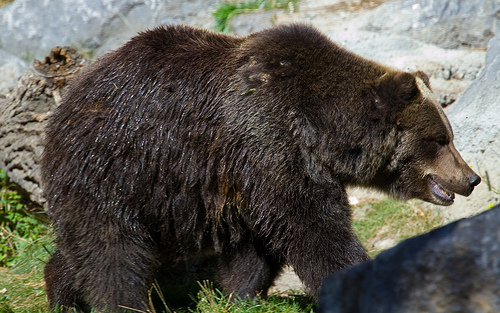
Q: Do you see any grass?
A: Yes, there is grass.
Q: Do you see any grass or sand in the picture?
A: Yes, there is grass.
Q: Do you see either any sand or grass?
A: Yes, there is grass.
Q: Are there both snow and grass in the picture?
A: No, there is grass but no snow.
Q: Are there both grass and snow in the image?
A: No, there is grass but no snow.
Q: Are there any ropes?
A: No, there are no ropes.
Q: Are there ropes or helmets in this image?
A: No, there are no ropes or helmets.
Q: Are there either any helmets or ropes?
A: No, there are no ropes or helmets.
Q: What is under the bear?
A: The grass is under the bear.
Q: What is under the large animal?
A: The grass is under the bear.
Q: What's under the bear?
A: The grass is under the bear.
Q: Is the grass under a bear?
A: Yes, the grass is under a bear.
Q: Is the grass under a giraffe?
A: No, the grass is under a bear.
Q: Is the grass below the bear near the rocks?
A: Yes, the grass is below the bear.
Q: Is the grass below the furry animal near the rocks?
A: Yes, the grass is below the bear.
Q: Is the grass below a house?
A: No, the grass is below the bear.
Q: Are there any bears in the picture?
A: Yes, there is a bear.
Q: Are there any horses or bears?
A: Yes, there is a bear.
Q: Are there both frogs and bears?
A: No, there is a bear but no frogs.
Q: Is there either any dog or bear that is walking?
A: Yes, the bear is walking.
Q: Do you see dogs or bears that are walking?
A: Yes, the bear is walking.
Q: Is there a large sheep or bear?
A: Yes, there is a large bear.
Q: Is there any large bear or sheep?
A: Yes, there is a large bear.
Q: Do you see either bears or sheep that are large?
A: Yes, the bear is large.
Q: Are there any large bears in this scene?
A: Yes, there is a large bear.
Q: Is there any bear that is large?
A: Yes, there is a bear that is large.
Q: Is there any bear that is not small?
A: Yes, there is a large bear.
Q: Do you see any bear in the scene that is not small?
A: Yes, there is a large bear.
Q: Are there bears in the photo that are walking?
A: Yes, there is a bear that is walking.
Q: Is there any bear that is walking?
A: Yes, there is a bear that is walking.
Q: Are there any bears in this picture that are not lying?
A: Yes, there is a bear that is walking.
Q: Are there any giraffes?
A: No, there are no giraffes.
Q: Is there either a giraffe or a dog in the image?
A: No, there are no giraffes or dogs.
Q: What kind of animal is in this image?
A: The animal is a bear.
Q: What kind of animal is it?
A: The animal is a bear.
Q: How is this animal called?
A: This is a bear.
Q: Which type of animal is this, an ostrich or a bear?
A: This is a bear.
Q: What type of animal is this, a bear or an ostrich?
A: This is a bear.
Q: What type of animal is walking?
A: The animal is a bear.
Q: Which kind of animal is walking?
A: The animal is a bear.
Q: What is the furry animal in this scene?
A: The animal is a bear.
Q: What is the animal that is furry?
A: The animal is a bear.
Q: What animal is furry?
A: The animal is a bear.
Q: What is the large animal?
A: The animal is a bear.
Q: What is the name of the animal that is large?
A: The animal is a bear.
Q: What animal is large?
A: The animal is a bear.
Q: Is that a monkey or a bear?
A: That is a bear.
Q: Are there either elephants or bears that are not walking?
A: No, there is a bear but it is walking.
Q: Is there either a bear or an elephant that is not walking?
A: No, there is a bear but it is walking.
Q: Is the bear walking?
A: Yes, the bear is walking.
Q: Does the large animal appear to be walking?
A: Yes, the bear is walking.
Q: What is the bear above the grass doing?
A: The bear is walking.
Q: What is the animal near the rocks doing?
A: The bear is walking.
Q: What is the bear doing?
A: The bear is walking.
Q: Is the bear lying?
A: No, the bear is walking.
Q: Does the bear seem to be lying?
A: No, the bear is walking.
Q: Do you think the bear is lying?
A: No, the bear is walking.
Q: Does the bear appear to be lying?
A: No, the bear is walking.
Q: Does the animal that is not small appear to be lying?
A: No, the bear is walking.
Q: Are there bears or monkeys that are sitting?
A: No, there is a bear but it is walking.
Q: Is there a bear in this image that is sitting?
A: No, there is a bear but it is walking.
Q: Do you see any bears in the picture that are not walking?
A: No, there is a bear but it is walking.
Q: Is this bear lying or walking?
A: The bear is walking.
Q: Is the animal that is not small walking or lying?
A: The bear is walking.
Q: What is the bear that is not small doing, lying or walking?
A: The bear is walking.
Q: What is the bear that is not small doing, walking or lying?
A: The bear is walking.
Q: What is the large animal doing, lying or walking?
A: The bear is walking.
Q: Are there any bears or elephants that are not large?
A: No, there is a bear but it is large.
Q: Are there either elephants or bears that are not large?
A: No, there is a bear but it is large.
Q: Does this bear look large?
A: Yes, the bear is large.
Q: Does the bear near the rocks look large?
A: Yes, the bear is large.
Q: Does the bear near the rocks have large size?
A: Yes, the bear is large.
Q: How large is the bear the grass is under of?
A: The bear is large.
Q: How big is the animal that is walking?
A: The bear is large.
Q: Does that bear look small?
A: No, the bear is large.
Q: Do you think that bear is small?
A: No, the bear is large.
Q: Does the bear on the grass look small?
A: No, the bear is large.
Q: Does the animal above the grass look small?
A: No, the bear is large.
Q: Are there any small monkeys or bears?
A: No, there is a bear but it is large.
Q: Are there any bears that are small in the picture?
A: No, there is a bear but it is large.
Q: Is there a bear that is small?
A: No, there is a bear but it is large.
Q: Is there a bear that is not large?
A: No, there is a bear but it is large.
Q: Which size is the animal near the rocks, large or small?
A: The bear is large.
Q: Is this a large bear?
A: Yes, this is a large bear.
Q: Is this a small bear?
A: No, this is a large bear.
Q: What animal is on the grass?
A: The bear is on the grass.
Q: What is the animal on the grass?
A: The animal is a bear.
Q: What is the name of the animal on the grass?
A: The animal is a bear.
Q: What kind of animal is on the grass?
A: The animal is a bear.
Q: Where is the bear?
A: The bear is on the grass.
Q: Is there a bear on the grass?
A: Yes, there is a bear on the grass.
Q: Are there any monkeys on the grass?
A: No, there is a bear on the grass.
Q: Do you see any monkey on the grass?
A: No, there is a bear on the grass.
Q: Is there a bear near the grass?
A: Yes, there is a bear near the grass.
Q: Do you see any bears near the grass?
A: Yes, there is a bear near the grass.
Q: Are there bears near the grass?
A: Yes, there is a bear near the grass.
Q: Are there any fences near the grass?
A: No, there is a bear near the grass.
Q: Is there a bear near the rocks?
A: Yes, there is a bear near the rocks.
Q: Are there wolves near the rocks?
A: No, there is a bear near the rocks.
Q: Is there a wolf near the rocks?
A: No, there is a bear near the rocks.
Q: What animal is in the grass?
A: The bear is in the grass.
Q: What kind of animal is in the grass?
A: The animal is a bear.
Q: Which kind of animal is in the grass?
A: The animal is a bear.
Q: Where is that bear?
A: The bear is in the grass.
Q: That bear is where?
A: The bear is in the grass.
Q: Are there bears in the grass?
A: Yes, there is a bear in the grass.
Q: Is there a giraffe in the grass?
A: No, there is a bear in the grass.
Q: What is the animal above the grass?
A: The animal is a bear.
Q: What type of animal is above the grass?
A: The animal is a bear.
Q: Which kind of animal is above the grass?
A: The animal is a bear.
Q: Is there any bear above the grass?
A: Yes, there is a bear above the grass.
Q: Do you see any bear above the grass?
A: Yes, there is a bear above the grass.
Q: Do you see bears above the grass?
A: Yes, there is a bear above the grass.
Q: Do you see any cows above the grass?
A: No, there is a bear above the grass.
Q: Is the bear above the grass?
A: Yes, the bear is above the grass.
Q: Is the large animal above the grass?
A: Yes, the bear is above the grass.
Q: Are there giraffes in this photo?
A: No, there are no giraffes.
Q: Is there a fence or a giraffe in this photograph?
A: No, there are no giraffes or fences.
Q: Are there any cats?
A: No, there are no cats.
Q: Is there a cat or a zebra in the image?
A: No, there are no cats or zebras.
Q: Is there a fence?
A: No, there are no fences.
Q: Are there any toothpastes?
A: No, there are no toothpastes.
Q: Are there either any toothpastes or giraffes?
A: No, there are no toothpastes or giraffes.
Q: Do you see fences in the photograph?
A: No, there are no fences.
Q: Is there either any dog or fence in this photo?
A: No, there are no fences or dogs.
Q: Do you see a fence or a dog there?
A: No, there are no fences or dogs.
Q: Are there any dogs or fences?
A: No, there are no fences or dogs.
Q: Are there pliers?
A: No, there are no pliers.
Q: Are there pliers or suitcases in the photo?
A: No, there are no pliers or suitcases.